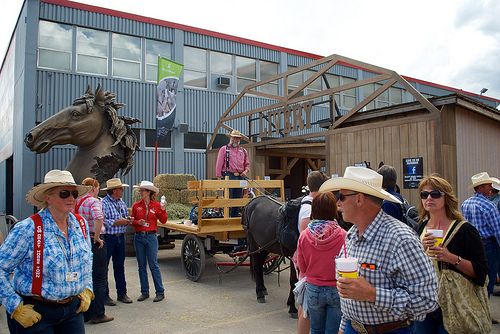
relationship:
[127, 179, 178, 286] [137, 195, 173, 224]
woman in red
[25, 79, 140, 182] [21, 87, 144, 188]
head of a horse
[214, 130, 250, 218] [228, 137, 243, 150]
man has gray hair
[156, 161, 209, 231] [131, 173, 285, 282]
hay on cart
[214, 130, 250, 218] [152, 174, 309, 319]
man standing on horsecart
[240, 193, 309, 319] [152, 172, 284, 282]
horse drawing cart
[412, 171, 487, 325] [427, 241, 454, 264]
woman has hand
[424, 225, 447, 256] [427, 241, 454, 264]
glass in hand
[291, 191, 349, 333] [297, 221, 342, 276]
girl wearing hoodie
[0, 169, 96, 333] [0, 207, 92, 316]
man wearing shirt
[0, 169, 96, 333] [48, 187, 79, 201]
man wearing sunglasses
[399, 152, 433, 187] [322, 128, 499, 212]
sign on wall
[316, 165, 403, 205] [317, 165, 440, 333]
hat on man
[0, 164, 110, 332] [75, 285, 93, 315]
man wearing glove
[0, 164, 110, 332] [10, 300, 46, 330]
man wearing glove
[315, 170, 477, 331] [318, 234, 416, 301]
man holding drink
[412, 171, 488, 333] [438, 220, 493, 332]
woman holding bag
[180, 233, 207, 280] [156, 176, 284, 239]
wheel on trailor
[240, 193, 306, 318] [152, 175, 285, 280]
horse in front of trailer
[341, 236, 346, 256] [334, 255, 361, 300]
straw in cup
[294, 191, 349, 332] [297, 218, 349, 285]
girl wearing hoodie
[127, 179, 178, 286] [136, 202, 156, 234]
woman wearing suspenders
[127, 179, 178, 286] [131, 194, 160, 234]
woman wearing shirt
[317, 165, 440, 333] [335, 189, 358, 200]
man wearing sunglasses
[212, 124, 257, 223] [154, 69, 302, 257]
man standing on trailer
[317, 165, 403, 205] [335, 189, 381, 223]
hat on head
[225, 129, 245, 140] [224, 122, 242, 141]
hat on man's head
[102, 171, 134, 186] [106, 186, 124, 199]
hat on head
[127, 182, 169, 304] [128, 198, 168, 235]
woman wearing shirt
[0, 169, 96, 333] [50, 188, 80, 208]
man wearing sunglasses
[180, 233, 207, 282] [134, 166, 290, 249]
wheel under cart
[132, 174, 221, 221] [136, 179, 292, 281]
hay bale on trailer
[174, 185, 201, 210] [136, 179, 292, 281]
hay bale on trailer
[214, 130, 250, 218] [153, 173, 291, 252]
man standing on trailer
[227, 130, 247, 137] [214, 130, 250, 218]
hat of man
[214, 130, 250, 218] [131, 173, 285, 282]
man standing on cart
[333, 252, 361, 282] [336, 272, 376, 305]
cup in hand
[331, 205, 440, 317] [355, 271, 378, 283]
shirt has pocket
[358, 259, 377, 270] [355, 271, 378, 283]
object in pocket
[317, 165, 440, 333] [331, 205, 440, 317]
man has shirt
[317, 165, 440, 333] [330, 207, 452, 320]
man has shirt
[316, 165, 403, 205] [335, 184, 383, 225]
hat on head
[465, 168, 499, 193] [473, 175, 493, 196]
hat on head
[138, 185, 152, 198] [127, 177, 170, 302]
head on man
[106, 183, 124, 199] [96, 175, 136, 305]
head on man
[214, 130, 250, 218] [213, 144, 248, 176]
man has shirt